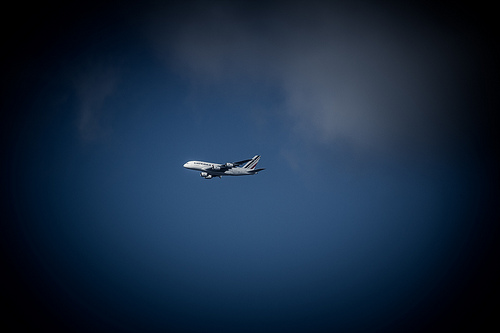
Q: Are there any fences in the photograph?
A: No, there are no fences.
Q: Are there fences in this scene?
A: No, there are no fences.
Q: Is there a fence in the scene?
A: No, there are no fences.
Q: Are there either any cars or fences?
A: No, there are no fences or cars.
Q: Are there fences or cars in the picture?
A: No, there are no fences or cars.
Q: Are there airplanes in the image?
A: Yes, there is an airplane.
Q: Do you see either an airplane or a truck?
A: Yes, there is an airplane.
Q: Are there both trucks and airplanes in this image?
A: No, there is an airplane but no trucks.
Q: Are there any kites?
A: No, there are no kites.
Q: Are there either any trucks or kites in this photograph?
A: No, there are no kites or trucks.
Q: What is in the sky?
A: The airplane is in the sky.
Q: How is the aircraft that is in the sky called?
A: The aircraft is an airplane.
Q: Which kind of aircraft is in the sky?
A: The aircraft is an airplane.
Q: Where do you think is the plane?
A: The plane is in the sky.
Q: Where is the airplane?
A: The plane is in the sky.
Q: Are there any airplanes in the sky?
A: Yes, there is an airplane in the sky.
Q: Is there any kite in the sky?
A: No, there is an airplane in the sky.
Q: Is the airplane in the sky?
A: Yes, the airplane is in the sky.